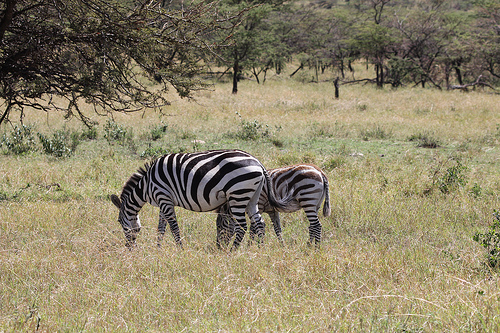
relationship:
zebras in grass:
[99, 142, 336, 265] [1, 88, 498, 332]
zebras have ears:
[99, 142, 336, 265] [104, 194, 133, 214]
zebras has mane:
[106, 149, 286, 249] [113, 160, 166, 196]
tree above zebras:
[6, 0, 224, 235] [99, 142, 336, 265]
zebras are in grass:
[99, 142, 336, 265] [1, 88, 498, 332]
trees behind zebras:
[142, 4, 498, 109] [99, 142, 336, 265]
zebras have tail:
[99, 142, 336, 265] [263, 173, 334, 218]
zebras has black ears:
[106, 149, 286, 249] [104, 194, 133, 214]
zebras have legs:
[99, 142, 336, 265] [152, 201, 324, 252]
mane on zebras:
[113, 160, 166, 196] [99, 142, 336, 265]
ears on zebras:
[104, 194, 133, 214] [106, 149, 286, 249]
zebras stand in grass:
[99, 142, 336, 265] [1, 88, 498, 332]